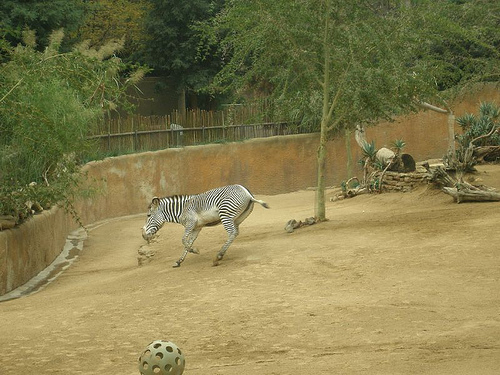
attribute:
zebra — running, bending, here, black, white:
[140, 184, 269, 267]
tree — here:
[189, 1, 442, 223]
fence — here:
[67, 109, 328, 156]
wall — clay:
[3, 82, 499, 299]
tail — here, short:
[253, 198, 270, 210]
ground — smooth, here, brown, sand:
[0, 154, 497, 375]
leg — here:
[217, 212, 239, 257]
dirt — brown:
[1, 164, 499, 374]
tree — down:
[432, 101, 499, 205]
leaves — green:
[191, 3, 499, 132]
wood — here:
[429, 161, 499, 205]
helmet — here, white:
[138, 339, 185, 374]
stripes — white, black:
[161, 196, 238, 213]